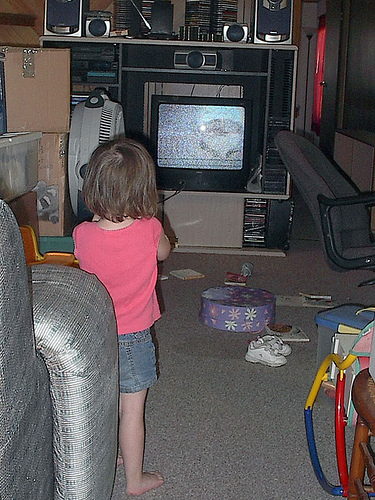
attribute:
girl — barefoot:
[72, 134, 173, 499]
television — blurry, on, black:
[148, 95, 256, 196]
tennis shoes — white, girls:
[243, 334, 292, 368]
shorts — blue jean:
[117, 327, 161, 393]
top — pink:
[72, 217, 167, 336]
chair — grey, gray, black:
[273, 130, 374, 288]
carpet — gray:
[111, 184, 374, 499]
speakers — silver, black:
[43, 1, 294, 45]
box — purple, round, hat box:
[200, 283, 276, 335]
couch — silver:
[2, 197, 119, 499]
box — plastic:
[2, 130, 43, 202]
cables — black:
[159, 178, 188, 210]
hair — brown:
[84, 138, 161, 224]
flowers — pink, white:
[197, 286, 275, 335]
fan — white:
[67, 86, 124, 222]